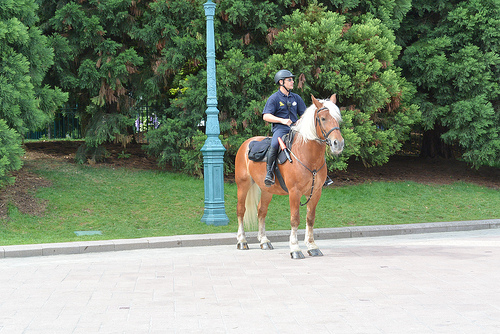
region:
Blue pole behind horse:
[187, 3, 240, 228]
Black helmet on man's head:
[266, 63, 301, 79]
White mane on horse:
[297, 108, 312, 138]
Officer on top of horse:
[225, 56, 360, 259]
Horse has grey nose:
[322, 132, 347, 154]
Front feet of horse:
[282, 233, 323, 264]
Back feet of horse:
[227, 231, 275, 256]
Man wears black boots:
[255, 170, 281, 186]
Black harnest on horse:
[237, 131, 267, 163]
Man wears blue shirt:
[270, 96, 303, 111]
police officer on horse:
[225, 40, 365, 270]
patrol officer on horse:
[222, 61, 348, 269]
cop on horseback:
[195, 60, 360, 268]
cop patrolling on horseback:
[230, 60, 376, 272]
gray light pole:
[195, 6, 232, 233]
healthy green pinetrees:
[352, 16, 497, 191]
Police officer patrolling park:
[175, 56, 405, 292]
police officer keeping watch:
[226, 47, 354, 277]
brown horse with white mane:
[225, 92, 373, 278]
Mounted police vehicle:
[220, 45, 347, 267]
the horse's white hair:
[293, 97, 343, 142]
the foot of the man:
[260, 175, 277, 186]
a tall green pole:
[202, 5, 226, 227]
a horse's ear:
[307, 92, 326, 109]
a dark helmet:
[275, 70, 294, 83]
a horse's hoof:
[290, 249, 308, 259]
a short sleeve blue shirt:
[264, 91, 305, 122]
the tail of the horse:
[243, 184, 260, 226]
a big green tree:
[402, 1, 499, 181]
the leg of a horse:
[288, 183, 304, 248]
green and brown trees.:
[311, 0, 418, 85]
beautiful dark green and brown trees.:
[45, 0, 177, 182]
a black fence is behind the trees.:
[135, 108, 155, 130]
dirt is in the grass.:
[2, 180, 48, 210]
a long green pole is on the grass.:
[200, 1, 231, 229]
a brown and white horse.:
[232, 95, 344, 267]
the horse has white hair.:
[295, 95, 343, 140]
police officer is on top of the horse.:
[257, 61, 307, 183]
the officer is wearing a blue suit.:
[263, 67, 305, 167]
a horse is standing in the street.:
[230, 94, 360, 259]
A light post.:
[188, 1, 227, 231]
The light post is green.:
[195, 2, 232, 224]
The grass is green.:
[70, 174, 165, 214]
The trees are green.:
[244, 8, 458, 57]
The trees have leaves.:
[236, 7, 438, 63]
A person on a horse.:
[223, 65, 386, 270]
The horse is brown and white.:
[203, 57, 365, 266]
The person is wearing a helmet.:
[261, 53, 302, 95]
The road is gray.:
[71, 270, 219, 327]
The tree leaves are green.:
[346, 13, 481, 104]